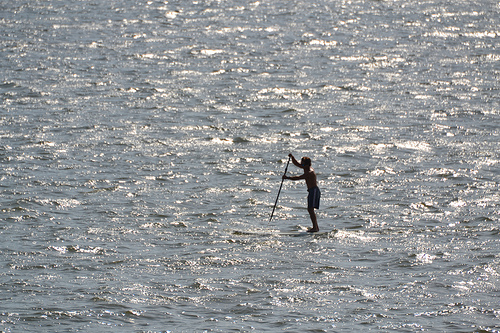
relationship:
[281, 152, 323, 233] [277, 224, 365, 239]
man on paddle board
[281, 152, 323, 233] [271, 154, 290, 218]
man holding paddle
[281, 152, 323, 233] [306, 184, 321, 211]
man wearing swimming trunks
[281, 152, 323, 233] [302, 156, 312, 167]
man has hair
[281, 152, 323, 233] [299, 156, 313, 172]
man has head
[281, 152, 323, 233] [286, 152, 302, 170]
man has arm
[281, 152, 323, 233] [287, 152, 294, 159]
man has hand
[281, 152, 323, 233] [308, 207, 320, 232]
man has leg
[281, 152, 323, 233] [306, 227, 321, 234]
man has foot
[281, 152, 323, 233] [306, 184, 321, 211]
man wearing shorts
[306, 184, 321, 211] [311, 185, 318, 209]
shorts have stripe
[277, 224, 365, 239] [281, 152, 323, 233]
paddle board under man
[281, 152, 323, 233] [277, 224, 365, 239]
man standing on paddle board